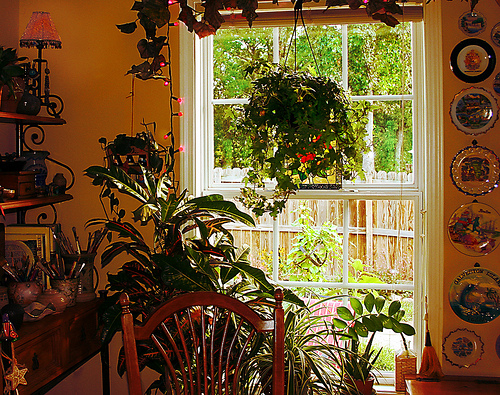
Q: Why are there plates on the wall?
A: For decoration.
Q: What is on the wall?
A: Plates.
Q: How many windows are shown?
A: One.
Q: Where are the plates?
A: On the wall.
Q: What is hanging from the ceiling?
A: A plant.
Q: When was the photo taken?
A: Daytime.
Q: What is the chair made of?
A: Wood.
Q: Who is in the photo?
A: Nobody.